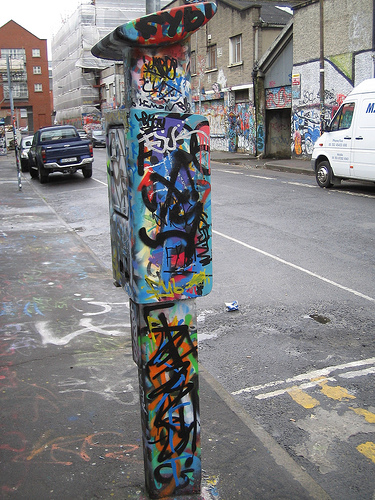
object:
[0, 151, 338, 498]
curb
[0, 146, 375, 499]
street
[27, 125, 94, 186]
truck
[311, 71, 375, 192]
van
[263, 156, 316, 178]
curb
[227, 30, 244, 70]
window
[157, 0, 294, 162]
building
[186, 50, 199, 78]
window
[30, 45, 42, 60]
window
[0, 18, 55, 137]
building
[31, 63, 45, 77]
window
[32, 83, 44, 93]
window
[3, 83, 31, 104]
window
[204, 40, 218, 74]
window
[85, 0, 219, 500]
post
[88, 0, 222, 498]
graffitti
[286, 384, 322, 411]
paint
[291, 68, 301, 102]
sign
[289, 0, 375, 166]
wall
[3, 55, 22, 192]
post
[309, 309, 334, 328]
spot